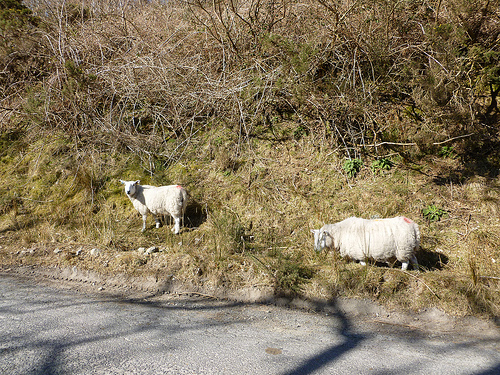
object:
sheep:
[118, 179, 193, 237]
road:
[0, 270, 500, 374]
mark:
[401, 214, 415, 226]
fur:
[339, 226, 407, 258]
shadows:
[0, 287, 260, 374]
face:
[117, 183, 140, 198]